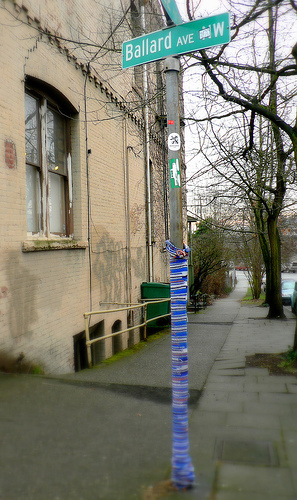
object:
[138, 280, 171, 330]
cans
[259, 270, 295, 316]
cars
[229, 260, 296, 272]
cars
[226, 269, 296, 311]
road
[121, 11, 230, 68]
sign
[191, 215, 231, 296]
bushes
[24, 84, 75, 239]
window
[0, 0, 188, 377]
building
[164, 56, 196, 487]
pole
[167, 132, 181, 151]
sticker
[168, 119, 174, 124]
sticker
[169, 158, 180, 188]
sticker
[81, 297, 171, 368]
fence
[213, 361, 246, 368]
raised block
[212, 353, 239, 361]
raised block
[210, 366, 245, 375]
raised block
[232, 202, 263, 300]
tree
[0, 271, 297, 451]
sidewalk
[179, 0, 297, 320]
tree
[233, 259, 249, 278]
cars road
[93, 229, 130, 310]
graffiti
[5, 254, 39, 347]
graffiti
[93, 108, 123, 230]
brick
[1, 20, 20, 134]
brick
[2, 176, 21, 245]
brick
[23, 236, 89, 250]
sill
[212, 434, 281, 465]
plate